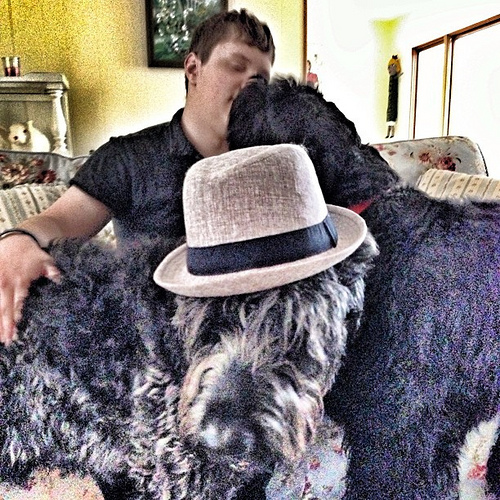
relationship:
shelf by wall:
[0, 71, 74, 157] [0, 0, 305, 157]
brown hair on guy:
[182, 15, 269, 52] [0, 9, 276, 342]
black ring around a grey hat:
[185, 211, 337, 275] [152, 144, 366, 296]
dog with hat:
[5, 220, 378, 498] [142, 132, 372, 305]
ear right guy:
[180, 47, 205, 87] [0, 9, 276, 342]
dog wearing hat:
[5, 220, 378, 498] [209, 147, 312, 281]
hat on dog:
[152, 142, 377, 297] [5, 220, 378, 498]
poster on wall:
[302, 46, 325, 97] [303, 7, 410, 157]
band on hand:
[1, 225, 39, 247] [2, 226, 63, 348]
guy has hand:
[0, 9, 276, 342] [2, 226, 63, 348]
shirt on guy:
[71, 107, 212, 239] [0, 9, 276, 342]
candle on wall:
[2, 52, 26, 74] [0, 0, 305, 157]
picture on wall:
[146, 0, 228, 70] [0, 0, 305, 157]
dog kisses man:
[225, 74, 500, 500] [171, 10, 277, 150]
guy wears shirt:
[0, 9, 276, 342] [67, 103, 204, 248]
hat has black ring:
[152, 142, 377, 297] [185, 211, 337, 276]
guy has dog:
[55, 5, 280, 179] [5, 220, 378, 498]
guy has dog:
[55, 5, 280, 179] [225, 74, 500, 500]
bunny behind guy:
[6, 118, 52, 153] [110, 11, 291, 151]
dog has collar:
[0, 138, 381, 498] [339, 178, 409, 219]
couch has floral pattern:
[0, 125, 480, 242] [415, 144, 467, 171]